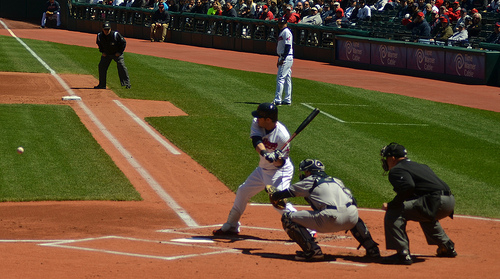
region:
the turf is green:
[187, 76, 229, 117]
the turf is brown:
[135, 142, 176, 194]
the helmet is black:
[252, 87, 283, 129]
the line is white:
[104, 149, 232, 231]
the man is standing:
[264, 10, 314, 110]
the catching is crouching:
[274, 151, 384, 274]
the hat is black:
[375, 132, 416, 159]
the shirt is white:
[244, 115, 299, 167]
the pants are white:
[217, 152, 312, 239]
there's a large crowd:
[242, 0, 485, 57]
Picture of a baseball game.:
[16, 3, 484, 275]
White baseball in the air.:
[10, 135, 35, 163]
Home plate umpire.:
[368, 125, 471, 267]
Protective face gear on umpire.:
[369, 132, 419, 173]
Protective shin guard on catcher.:
[267, 205, 330, 265]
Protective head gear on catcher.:
[296, 154, 331, 180]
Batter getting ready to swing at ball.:
[212, 94, 304, 254]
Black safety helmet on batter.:
[245, 92, 288, 134]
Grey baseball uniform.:
[281, 167, 378, 277]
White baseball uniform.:
[212, 108, 299, 250]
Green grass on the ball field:
[210, 106, 317, 253]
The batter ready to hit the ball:
[251, 85, 350, 212]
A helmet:
[249, 87, 281, 126]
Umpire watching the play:
[374, 97, 424, 274]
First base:
[48, 58, 98, 168]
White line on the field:
[152, 147, 203, 267]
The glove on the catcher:
[245, 168, 315, 213]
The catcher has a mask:
[260, 148, 362, 266]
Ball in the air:
[16, 133, 23, 162]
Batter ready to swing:
[227, 78, 374, 217]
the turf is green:
[35, 129, 80, 165]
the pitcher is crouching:
[295, 152, 363, 254]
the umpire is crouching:
[373, 132, 465, 260]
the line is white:
[101, 140, 213, 197]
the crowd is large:
[215, 0, 497, 42]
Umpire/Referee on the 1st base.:
[92, 18, 134, 98]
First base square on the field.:
[59, 88, 83, 101]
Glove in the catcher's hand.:
[266, 173, 286, 213]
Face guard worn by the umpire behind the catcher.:
[378, 144, 392, 170]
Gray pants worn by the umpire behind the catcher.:
[383, 198, 458, 250]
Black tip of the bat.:
[293, 106, 323, 142]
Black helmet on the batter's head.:
[253, 96, 279, 121]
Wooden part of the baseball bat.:
[266, 131, 304, 157]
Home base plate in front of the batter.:
[173, 226, 223, 245]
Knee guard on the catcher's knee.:
[281, 208, 318, 254]